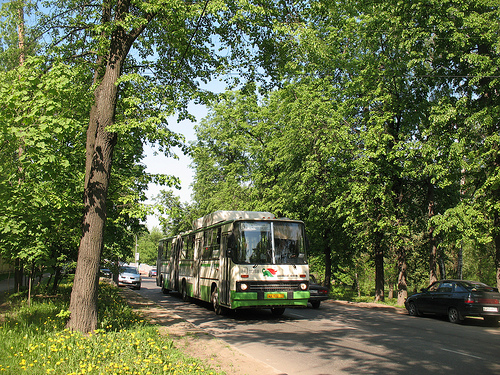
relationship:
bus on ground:
[156, 210, 311, 315] [0, 271, 500, 374]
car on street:
[404, 279, 500, 324] [135, 269, 499, 374]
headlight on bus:
[300, 283, 307, 290] [148, 207, 327, 325]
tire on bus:
[208, 281, 221, 313] [156, 210, 311, 315]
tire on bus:
[154, 273, 190, 296] [141, 213, 319, 315]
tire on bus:
[162, 276, 170, 294] [148, 207, 327, 325]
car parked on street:
[400, 269, 498, 330] [108, 264, 498, 374]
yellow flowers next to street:
[0, 309, 211, 374] [220, 318, 474, 370]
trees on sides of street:
[48, 32, 448, 346] [108, 264, 498, 374]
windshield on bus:
[224, 219, 306, 266] [156, 210, 311, 315]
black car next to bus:
[309, 274, 329, 308] [156, 210, 311, 315]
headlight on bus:
[240, 283, 248, 291] [107, 122, 344, 322]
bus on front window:
[156, 210, 311, 315] [227, 217, 309, 266]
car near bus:
[404, 279, 500, 324] [171, 225, 272, 314]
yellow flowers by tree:
[7, 315, 212, 373] [40, 0, 172, 327]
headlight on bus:
[239, 282, 253, 294] [150, 213, 309, 311]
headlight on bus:
[296, 280, 307, 290] [150, 213, 309, 311]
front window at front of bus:
[227, 217, 307, 264] [156, 210, 311, 315]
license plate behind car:
[482, 306, 499, 315] [401, 256, 497, 323]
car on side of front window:
[404, 279, 500, 324] [227, 217, 309, 266]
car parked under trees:
[404, 279, 500, 324] [319, 2, 496, 305]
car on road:
[404, 279, 500, 324] [157, 268, 499, 370]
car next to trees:
[98, 258, 168, 313] [322, 94, 459, 279]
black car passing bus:
[306, 276, 327, 307] [156, 210, 311, 315]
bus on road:
[156, 210, 311, 315] [292, 367, 412, 375]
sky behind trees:
[186, 73, 223, 134] [161, 74, 456, 278]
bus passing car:
[143, 210, 340, 314] [403, 265, 489, 310]